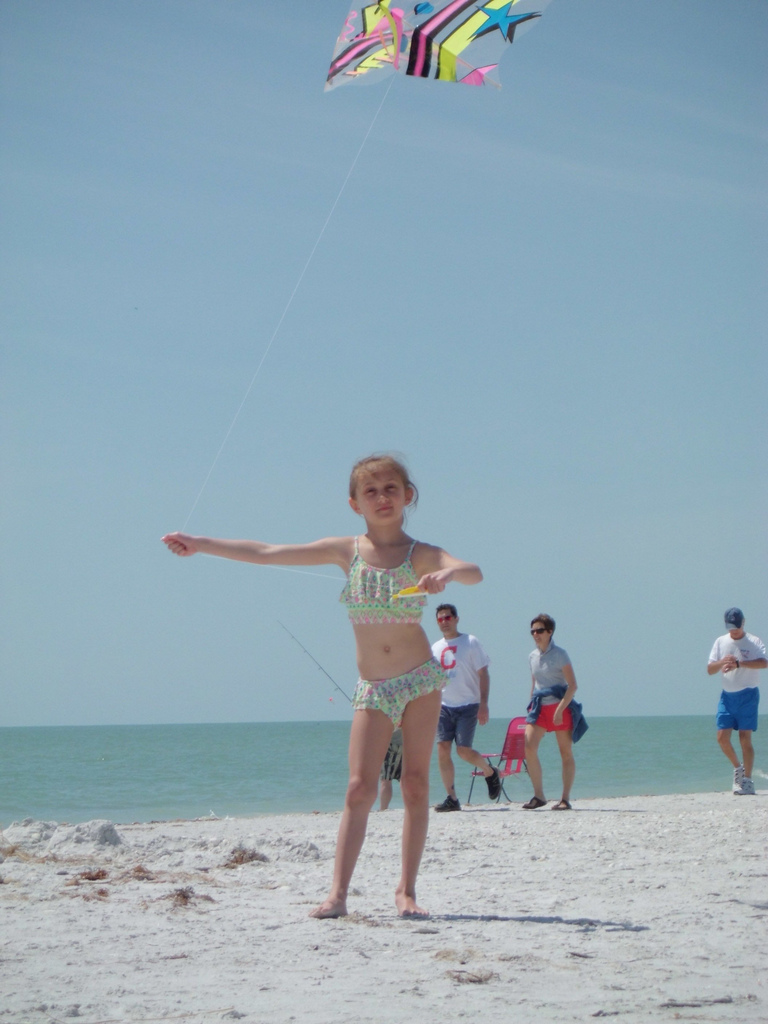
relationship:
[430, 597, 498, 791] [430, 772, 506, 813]
man wearing shoes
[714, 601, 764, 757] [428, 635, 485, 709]
man wearing shirt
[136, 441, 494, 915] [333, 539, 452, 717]
girl wearing bikini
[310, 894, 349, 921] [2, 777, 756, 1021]
foot on beach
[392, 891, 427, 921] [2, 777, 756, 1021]
foot on beach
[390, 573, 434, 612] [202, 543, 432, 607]
holder for kitestring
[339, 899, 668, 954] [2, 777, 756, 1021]
shadow on beach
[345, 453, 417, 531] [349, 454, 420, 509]
girl has girl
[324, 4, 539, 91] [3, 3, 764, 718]
kite flying sky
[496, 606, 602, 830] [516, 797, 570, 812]
woman wearing sandals